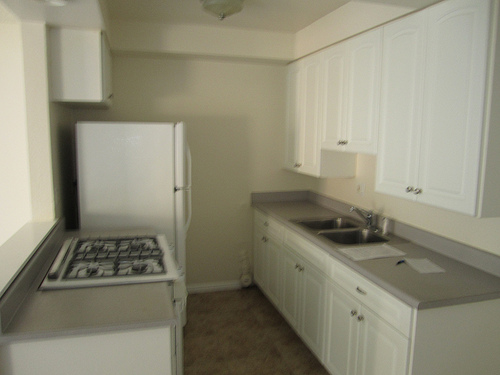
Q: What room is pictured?
A: It is a kitchen.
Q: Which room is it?
A: It is a kitchen.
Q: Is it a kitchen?
A: Yes, it is a kitchen.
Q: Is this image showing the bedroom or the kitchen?
A: It is showing the kitchen.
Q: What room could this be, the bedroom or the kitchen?
A: It is the kitchen.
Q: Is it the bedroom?
A: No, it is the kitchen.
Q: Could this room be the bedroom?
A: No, it is the kitchen.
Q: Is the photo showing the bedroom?
A: No, the picture is showing the kitchen.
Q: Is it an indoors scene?
A: Yes, it is indoors.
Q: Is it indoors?
A: Yes, it is indoors.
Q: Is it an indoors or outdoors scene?
A: It is indoors.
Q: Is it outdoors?
A: No, it is indoors.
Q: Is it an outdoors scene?
A: No, it is indoors.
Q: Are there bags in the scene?
A: No, there are no bags.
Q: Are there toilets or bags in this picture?
A: No, there are no bags or toilets.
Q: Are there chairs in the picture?
A: No, there are no chairs.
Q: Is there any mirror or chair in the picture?
A: No, there are no chairs or mirrors.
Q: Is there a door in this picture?
A: Yes, there is a door.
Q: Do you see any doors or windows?
A: Yes, there is a door.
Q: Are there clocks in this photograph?
A: No, there are no clocks.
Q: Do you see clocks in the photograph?
A: No, there are no clocks.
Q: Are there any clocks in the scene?
A: No, there are no clocks.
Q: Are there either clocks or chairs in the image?
A: No, there are no clocks or chairs.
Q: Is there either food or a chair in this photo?
A: No, there are no chairs or food.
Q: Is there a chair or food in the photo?
A: No, there are no chairs or food.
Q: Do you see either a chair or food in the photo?
A: No, there are no chairs or food.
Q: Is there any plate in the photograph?
A: No, there are no plates.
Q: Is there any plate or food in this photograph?
A: No, there are no plates or food.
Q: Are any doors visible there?
A: Yes, there is a door.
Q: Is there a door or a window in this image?
A: Yes, there is a door.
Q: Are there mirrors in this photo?
A: No, there are no mirrors.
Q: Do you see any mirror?
A: No, there are no mirrors.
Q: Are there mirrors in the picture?
A: No, there are no mirrors.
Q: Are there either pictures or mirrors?
A: No, there are no mirrors or pictures.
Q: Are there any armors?
A: No, there are no armors.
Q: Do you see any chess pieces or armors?
A: No, there are no armors or chess pieces.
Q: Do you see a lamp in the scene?
A: Yes, there is a lamp.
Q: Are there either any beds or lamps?
A: Yes, there is a lamp.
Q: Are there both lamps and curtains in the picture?
A: No, there is a lamp but no curtains.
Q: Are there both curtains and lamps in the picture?
A: No, there is a lamp but no curtains.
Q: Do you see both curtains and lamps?
A: No, there is a lamp but no curtains.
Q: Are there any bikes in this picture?
A: No, there are no bikes.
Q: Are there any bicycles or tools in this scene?
A: No, there are no bicycles or tools.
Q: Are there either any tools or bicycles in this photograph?
A: No, there are no bicycles or tools.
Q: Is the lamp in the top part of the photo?
A: Yes, the lamp is in the top of the image.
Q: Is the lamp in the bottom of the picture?
A: No, the lamp is in the top of the image.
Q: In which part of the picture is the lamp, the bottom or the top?
A: The lamp is in the top of the image.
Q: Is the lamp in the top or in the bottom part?
A: The lamp is in the top of the image.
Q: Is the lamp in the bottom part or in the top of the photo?
A: The lamp is in the top of the image.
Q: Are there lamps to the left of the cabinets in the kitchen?
A: Yes, there is a lamp to the left of the cabinets.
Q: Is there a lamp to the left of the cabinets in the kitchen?
A: Yes, there is a lamp to the left of the cabinets.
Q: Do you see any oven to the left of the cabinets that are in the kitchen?
A: No, there is a lamp to the left of the cabinets.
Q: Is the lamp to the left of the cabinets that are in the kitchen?
A: Yes, the lamp is to the left of the cabinets.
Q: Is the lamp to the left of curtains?
A: No, the lamp is to the left of the cabinets.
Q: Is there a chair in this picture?
A: No, there are no chairs.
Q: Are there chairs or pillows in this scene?
A: No, there are no chairs or pillows.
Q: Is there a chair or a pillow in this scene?
A: No, there are no chairs or pillows.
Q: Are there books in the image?
A: No, there are no books.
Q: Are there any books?
A: No, there are no books.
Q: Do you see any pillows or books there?
A: No, there are no books or pillows.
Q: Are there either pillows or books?
A: No, there are no books or pillows.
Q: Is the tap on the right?
A: Yes, the tap is on the right of the image.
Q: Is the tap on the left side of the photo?
A: No, the tap is on the right of the image.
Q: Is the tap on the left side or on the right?
A: The tap is on the right of the image.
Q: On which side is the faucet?
A: The faucet is on the right of the image.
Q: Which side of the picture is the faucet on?
A: The faucet is on the right of the image.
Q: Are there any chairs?
A: No, there are no chairs.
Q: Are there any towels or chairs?
A: No, there are no chairs or towels.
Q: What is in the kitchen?
A: The cabinets are in the kitchen.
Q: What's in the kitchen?
A: The cabinets are in the kitchen.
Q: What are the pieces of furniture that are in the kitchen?
A: The pieces of furniture are cabinets.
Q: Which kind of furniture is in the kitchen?
A: The pieces of furniture are cabinets.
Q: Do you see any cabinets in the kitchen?
A: Yes, there are cabinets in the kitchen.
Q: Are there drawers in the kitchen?
A: No, there are cabinets in the kitchen.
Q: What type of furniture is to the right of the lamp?
A: The pieces of furniture are cabinets.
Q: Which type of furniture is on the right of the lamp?
A: The pieces of furniture are cabinets.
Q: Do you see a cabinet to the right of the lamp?
A: Yes, there are cabinets to the right of the lamp.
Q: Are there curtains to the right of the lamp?
A: No, there are cabinets to the right of the lamp.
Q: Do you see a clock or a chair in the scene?
A: No, there are no chairs or clocks.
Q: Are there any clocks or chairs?
A: No, there are no chairs or clocks.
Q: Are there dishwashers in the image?
A: No, there are no dishwashers.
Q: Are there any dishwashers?
A: No, there are no dishwashers.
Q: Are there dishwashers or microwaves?
A: No, there are no dishwashers or microwaves.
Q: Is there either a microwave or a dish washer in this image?
A: No, there are no dishwashers or microwaves.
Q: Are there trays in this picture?
A: No, there are no trays.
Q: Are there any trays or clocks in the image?
A: No, there are no trays or clocks.